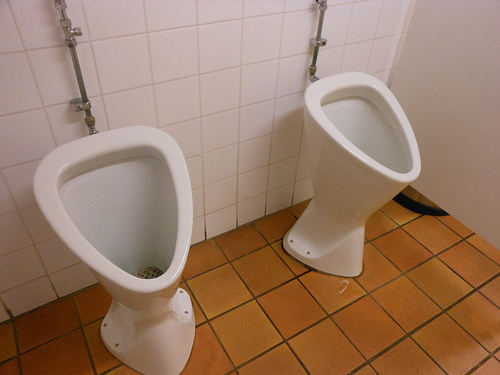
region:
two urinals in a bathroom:
[38, 73, 417, 360]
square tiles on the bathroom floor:
[221, 290, 457, 367]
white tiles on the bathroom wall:
[196, 5, 261, 188]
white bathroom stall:
[437, 3, 491, 203]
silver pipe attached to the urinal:
[49, 0, 94, 132]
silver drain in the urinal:
[134, 265, 164, 278]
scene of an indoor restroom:
[20, 10, 488, 368]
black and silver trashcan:
[396, 186, 452, 220]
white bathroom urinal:
[288, 70, 418, 282]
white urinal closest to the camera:
[29, 124, 202, 373]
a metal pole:
[53, 10, 104, 127]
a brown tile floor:
[223, 278, 498, 365]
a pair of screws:
[98, 316, 122, 359]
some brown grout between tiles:
[386, 263, 478, 357]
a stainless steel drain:
[132, 260, 165, 283]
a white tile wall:
[166, 6, 303, 206]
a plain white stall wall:
[408, 8, 498, 235]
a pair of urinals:
[45, 66, 445, 373]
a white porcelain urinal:
[281, 65, 422, 282]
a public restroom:
[22, 0, 486, 361]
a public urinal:
[39, 41, 476, 339]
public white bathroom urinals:
[33, 68, 473, 318]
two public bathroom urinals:
[57, 75, 492, 361]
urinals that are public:
[34, 51, 496, 283]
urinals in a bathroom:
[51, 75, 497, 305]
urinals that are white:
[64, 80, 496, 330]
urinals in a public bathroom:
[64, 126, 495, 322]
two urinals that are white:
[22, 66, 490, 373]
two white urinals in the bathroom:
[44, 73, 496, 315]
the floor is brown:
[227, 248, 362, 354]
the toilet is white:
[8, 110, 233, 373]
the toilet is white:
[275, 58, 430, 280]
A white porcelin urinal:
[279, 66, 423, 278]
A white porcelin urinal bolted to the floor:
[32, 123, 198, 374]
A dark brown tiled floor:
[1, 192, 498, 373]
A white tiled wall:
[0, 1, 417, 329]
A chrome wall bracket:
[66, 94, 96, 118]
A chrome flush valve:
[53, 15, 87, 51]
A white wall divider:
[384, 0, 498, 250]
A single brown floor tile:
[327, 291, 409, 364]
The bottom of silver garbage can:
[392, 180, 451, 223]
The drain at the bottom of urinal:
[129, 261, 167, 283]